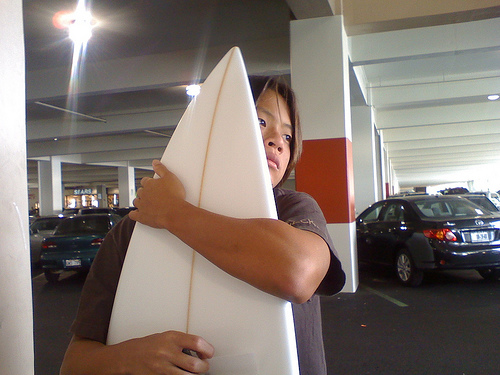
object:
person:
[58, 75, 347, 373]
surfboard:
[106, 43, 301, 374]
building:
[1, 2, 499, 374]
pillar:
[289, 14, 360, 294]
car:
[357, 195, 499, 285]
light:
[436, 229, 458, 242]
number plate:
[470, 230, 488, 245]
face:
[256, 86, 290, 190]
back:
[408, 197, 499, 273]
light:
[52, 10, 94, 46]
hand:
[129, 159, 184, 227]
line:
[360, 275, 410, 306]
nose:
[264, 126, 280, 149]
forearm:
[168, 203, 301, 301]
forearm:
[61, 330, 137, 374]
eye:
[258, 117, 265, 127]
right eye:
[281, 132, 290, 141]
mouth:
[266, 153, 281, 169]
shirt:
[69, 187, 345, 373]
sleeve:
[69, 209, 137, 343]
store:
[63, 187, 104, 209]